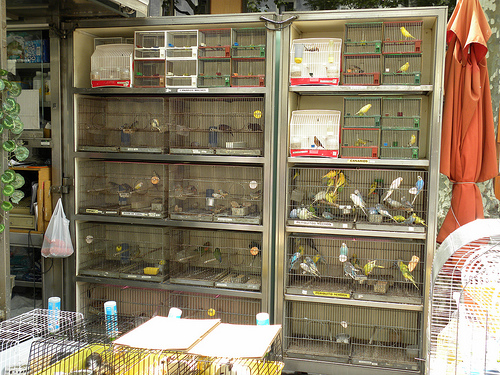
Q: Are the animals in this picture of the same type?
A: Yes, all the animals are birds.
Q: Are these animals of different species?
A: No, all the animals are birds.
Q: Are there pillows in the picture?
A: No, there are no pillows.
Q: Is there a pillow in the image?
A: No, there are no pillows.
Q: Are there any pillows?
A: No, there are no pillows.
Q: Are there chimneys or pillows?
A: No, there are no pillows or chimneys.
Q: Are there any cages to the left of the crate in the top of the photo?
A: Yes, there is a cage to the left of the crate.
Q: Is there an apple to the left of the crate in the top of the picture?
A: No, there is a cage to the left of the crate.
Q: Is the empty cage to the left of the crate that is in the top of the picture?
A: Yes, the cage is to the left of the crate.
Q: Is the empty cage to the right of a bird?
A: No, the cage is to the left of a bird.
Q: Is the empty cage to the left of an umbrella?
A: Yes, the cage is to the left of an umbrella.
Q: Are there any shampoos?
A: No, there are no shampoos.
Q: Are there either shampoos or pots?
A: No, there are no shampoos or pots.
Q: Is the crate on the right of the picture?
A: Yes, the crate is on the right of the image.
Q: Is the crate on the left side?
A: No, the crate is on the right of the image.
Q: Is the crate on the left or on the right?
A: The crate is on the right of the image.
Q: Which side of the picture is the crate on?
A: The crate is on the right of the image.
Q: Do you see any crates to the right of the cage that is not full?
A: Yes, there is a crate to the right of the cage.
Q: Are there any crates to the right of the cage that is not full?
A: Yes, there is a crate to the right of the cage.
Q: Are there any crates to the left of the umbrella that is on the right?
A: Yes, there is a crate to the left of the umbrella.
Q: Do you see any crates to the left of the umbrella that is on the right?
A: Yes, there is a crate to the left of the umbrella.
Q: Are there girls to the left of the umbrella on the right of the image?
A: No, there is a crate to the left of the umbrella.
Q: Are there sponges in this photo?
A: No, there are no sponges.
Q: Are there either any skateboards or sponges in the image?
A: No, there are no sponges or skateboards.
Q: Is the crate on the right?
A: Yes, the crate is on the right of the image.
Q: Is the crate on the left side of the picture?
A: No, the crate is on the right of the image.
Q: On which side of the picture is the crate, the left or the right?
A: The crate is on the right of the image.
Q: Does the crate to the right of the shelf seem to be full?
A: Yes, the crate is full.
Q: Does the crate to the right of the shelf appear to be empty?
A: No, the crate is full.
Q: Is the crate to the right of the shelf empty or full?
A: The crate is full.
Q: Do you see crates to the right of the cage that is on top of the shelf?
A: Yes, there is a crate to the right of the cage.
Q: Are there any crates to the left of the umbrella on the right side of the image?
A: Yes, there is a crate to the left of the umbrella.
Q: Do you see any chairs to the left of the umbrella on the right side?
A: No, there is a crate to the left of the umbrella.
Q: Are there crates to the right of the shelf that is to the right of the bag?
A: Yes, there is a crate to the right of the shelf.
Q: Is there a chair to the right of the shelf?
A: No, there is a crate to the right of the shelf.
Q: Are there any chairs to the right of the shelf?
A: No, there is a crate to the right of the shelf.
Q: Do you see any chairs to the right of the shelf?
A: No, there is a crate to the right of the shelf.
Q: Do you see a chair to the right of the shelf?
A: No, there is a crate to the right of the shelf.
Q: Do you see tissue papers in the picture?
A: No, there are no tissue papers.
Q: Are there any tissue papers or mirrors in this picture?
A: No, there are no tissue papers or mirrors.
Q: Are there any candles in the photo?
A: No, there are no candles.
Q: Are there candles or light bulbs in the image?
A: No, there are no candles or light bulbs.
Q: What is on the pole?
A: The vine is on the pole.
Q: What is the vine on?
A: The vine is on the pole.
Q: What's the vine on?
A: The vine is on the pole.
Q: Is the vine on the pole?
A: Yes, the vine is on the pole.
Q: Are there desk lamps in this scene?
A: No, there are no desk lamps.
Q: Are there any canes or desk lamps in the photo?
A: No, there are no desk lamps or canes.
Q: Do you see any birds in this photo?
A: Yes, there is a bird.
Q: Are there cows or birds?
A: Yes, there is a bird.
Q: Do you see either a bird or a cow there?
A: Yes, there is a bird.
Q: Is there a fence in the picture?
A: No, there are no fences.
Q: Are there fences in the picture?
A: No, there are no fences.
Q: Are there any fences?
A: No, there are no fences.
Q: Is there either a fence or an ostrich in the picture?
A: No, there are no fences or ostriches.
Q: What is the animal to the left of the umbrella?
A: The animal is a bird.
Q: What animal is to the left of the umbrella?
A: The animal is a bird.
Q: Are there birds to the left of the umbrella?
A: Yes, there is a bird to the left of the umbrella.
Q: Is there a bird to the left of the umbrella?
A: Yes, there is a bird to the left of the umbrella.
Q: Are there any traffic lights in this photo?
A: No, there are no traffic lights.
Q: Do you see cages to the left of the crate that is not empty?
A: Yes, there is a cage to the left of the crate.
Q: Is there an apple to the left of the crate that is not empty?
A: No, there is a cage to the left of the crate.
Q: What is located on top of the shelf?
A: The cage is on top of the shelf.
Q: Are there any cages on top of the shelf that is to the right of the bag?
A: Yes, there is a cage on top of the shelf.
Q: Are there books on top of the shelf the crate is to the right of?
A: No, there is a cage on top of the shelf.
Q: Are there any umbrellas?
A: Yes, there is an umbrella.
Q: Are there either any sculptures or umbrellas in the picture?
A: Yes, there is an umbrella.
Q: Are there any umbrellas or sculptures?
A: Yes, there is an umbrella.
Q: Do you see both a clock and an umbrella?
A: No, there is an umbrella but no clocks.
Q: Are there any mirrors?
A: No, there are no mirrors.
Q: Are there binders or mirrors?
A: No, there are no mirrors or binders.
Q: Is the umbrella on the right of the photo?
A: Yes, the umbrella is on the right of the image.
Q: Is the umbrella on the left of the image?
A: No, the umbrella is on the right of the image.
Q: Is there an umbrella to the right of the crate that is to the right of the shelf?
A: Yes, there is an umbrella to the right of the crate.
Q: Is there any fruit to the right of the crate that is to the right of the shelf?
A: No, there is an umbrella to the right of the crate.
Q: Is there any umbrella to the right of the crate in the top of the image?
A: Yes, there is an umbrella to the right of the crate.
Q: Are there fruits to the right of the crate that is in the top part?
A: No, there is an umbrella to the right of the crate.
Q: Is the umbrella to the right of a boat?
A: No, the umbrella is to the right of the crate.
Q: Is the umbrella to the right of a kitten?
A: No, the umbrella is to the right of a bird.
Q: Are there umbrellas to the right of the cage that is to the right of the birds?
A: Yes, there is an umbrella to the right of the cage.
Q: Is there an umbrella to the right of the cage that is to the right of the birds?
A: Yes, there is an umbrella to the right of the cage.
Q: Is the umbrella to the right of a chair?
A: No, the umbrella is to the right of a cage.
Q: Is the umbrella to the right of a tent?
A: No, the umbrella is to the right of a bird.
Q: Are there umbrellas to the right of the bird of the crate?
A: Yes, there is an umbrella to the right of the bird.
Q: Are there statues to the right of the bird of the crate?
A: No, there is an umbrella to the right of the bird.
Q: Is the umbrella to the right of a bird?
A: Yes, the umbrella is to the right of a bird.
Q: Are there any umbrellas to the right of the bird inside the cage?
A: Yes, there is an umbrella to the right of the bird.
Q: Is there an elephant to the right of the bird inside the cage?
A: No, there is an umbrella to the right of the bird.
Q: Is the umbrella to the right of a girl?
A: No, the umbrella is to the right of the bird.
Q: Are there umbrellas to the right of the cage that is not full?
A: Yes, there is an umbrella to the right of the cage.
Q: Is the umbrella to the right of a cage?
A: Yes, the umbrella is to the right of a cage.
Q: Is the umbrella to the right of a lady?
A: No, the umbrella is to the right of a cage.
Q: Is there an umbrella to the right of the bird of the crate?
A: Yes, there is an umbrella to the right of the bird.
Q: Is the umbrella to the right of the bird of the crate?
A: Yes, the umbrella is to the right of the bird.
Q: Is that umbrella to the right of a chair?
A: No, the umbrella is to the right of a bird.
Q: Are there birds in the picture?
A: Yes, there is a bird.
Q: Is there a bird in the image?
A: Yes, there is a bird.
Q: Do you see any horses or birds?
A: Yes, there is a bird.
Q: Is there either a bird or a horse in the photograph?
A: Yes, there is a bird.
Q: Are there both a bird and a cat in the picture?
A: No, there is a bird but no cats.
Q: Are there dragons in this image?
A: No, there are no dragons.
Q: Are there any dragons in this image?
A: No, there are no dragons.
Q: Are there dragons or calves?
A: No, there are no dragons or calves.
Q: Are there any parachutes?
A: No, there are no parachutes.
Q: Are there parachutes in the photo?
A: No, there are no parachutes.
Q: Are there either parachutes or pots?
A: No, there are no parachutes or pots.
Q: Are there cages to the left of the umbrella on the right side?
A: Yes, there is a cage to the left of the umbrella.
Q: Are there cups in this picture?
A: No, there are no cups.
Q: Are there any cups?
A: No, there are no cups.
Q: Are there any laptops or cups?
A: No, there are no cups or laptops.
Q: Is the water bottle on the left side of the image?
A: Yes, the water bottle is on the left of the image.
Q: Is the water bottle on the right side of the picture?
A: No, the water bottle is on the left of the image.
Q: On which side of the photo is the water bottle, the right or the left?
A: The water bottle is on the left of the image.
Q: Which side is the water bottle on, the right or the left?
A: The water bottle is on the left of the image.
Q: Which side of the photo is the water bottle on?
A: The water bottle is on the left of the image.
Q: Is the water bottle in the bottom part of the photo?
A: Yes, the water bottle is in the bottom of the image.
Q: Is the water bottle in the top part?
A: No, the water bottle is in the bottom of the image.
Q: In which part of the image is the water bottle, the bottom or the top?
A: The water bottle is in the bottom of the image.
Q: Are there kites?
A: No, there are no kites.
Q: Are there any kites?
A: No, there are no kites.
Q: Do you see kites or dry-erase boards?
A: No, there are no kites or dry-erase boards.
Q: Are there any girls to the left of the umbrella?
A: No, there is a cage to the left of the umbrella.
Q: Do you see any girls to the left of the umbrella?
A: No, there is a cage to the left of the umbrella.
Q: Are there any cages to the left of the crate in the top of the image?
A: Yes, there is a cage to the left of the crate.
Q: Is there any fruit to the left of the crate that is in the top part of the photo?
A: No, there is a cage to the left of the crate.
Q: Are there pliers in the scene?
A: No, there are no pliers.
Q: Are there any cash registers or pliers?
A: No, there are no pliers or cash registers.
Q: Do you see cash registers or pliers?
A: No, there are no pliers or cash registers.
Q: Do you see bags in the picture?
A: Yes, there is a bag.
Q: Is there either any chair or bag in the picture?
A: Yes, there is a bag.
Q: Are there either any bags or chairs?
A: Yes, there is a bag.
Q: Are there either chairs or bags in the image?
A: Yes, there is a bag.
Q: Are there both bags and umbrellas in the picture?
A: Yes, there are both a bag and an umbrella.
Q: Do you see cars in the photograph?
A: No, there are no cars.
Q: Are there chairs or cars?
A: No, there are no cars or chairs.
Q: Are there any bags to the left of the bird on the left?
A: Yes, there is a bag to the left of the bird.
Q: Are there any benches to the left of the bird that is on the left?
A: No, there is a bag to the left of the bird.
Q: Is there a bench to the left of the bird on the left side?
A: No, there is a bag to the left of the bird.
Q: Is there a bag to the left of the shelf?
A: Yes, there is a bag to the left of the shelf.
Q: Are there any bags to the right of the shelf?
A: No, the bag is to the left of the shelf.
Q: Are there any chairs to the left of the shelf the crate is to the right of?
A: No, there is a bag to the left of the shelf.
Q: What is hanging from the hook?
A: The bag is hanging from the hook.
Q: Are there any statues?
A: No, there are no statues.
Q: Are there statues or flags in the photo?
A: No, there are no statues or flags.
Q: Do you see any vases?
A: No, there are no vases.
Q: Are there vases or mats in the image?
A: No, there are no vases or mats.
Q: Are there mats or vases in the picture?
A: No, there are no vases or mats.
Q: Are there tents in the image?
A: No, there are no tents.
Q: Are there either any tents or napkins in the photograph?
A: No, there are no tents or napkins.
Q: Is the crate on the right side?
A: Yes, the crate is on the right of the image.